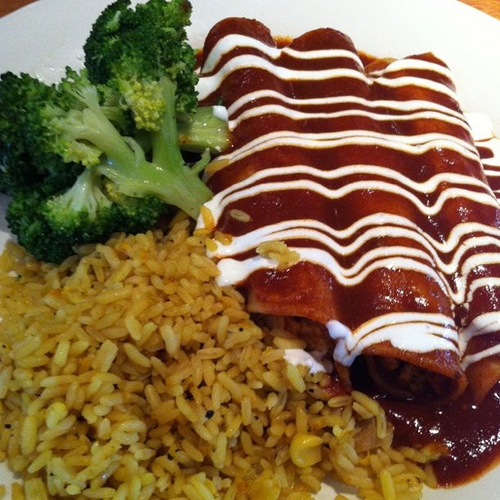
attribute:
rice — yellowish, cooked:
[0, 205, 451, 495]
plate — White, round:
[1, 0, 498, 498]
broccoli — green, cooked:
[4, 0, 231, 263]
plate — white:
[420, 9, 484, 41]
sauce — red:
[347, 321, 491, 474]